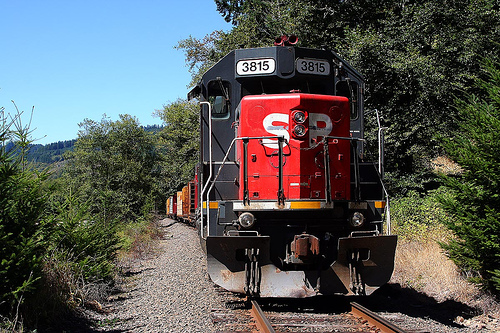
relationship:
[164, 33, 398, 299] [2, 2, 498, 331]
train in countryside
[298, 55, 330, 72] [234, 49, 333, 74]
number 3815 on top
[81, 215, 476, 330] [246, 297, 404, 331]
gravel on railroad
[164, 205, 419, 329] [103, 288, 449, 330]
crossties under track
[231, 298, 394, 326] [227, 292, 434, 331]
rails in track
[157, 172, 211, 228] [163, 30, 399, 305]
cars on train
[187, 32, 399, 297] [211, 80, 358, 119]
engine has windshields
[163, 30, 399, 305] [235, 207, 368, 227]
train has headlight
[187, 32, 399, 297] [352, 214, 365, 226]
engine has headlight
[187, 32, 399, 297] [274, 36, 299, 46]
engine has horn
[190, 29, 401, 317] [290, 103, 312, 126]
engine has headlight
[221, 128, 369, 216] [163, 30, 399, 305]
metal railing on train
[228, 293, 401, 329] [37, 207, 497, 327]
tracks on hillside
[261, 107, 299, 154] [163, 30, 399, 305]
letter s on left of train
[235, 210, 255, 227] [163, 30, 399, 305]
headlight of train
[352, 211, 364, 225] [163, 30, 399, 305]
headlight ob train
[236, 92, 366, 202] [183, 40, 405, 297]
structure on train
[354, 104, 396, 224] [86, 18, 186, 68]
brush extending sky